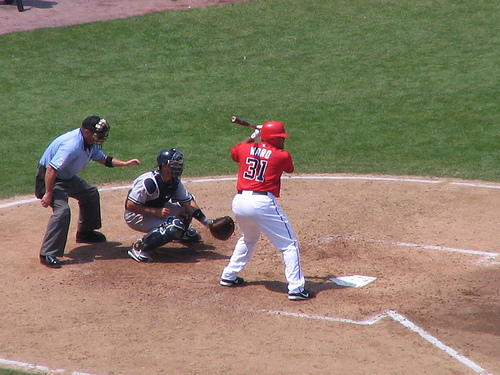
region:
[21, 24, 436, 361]
this is at a baseball field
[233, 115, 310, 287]
this is a baseball player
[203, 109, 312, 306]
this is a batter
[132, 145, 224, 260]
this is a catcher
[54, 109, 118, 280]
this is an umpire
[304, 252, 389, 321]
this is home plate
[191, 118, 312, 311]
the man is holding a bat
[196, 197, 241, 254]
this is a catchers mitt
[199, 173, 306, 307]
the man has white pants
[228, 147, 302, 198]
the man has a red jersey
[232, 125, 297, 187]
Man wearing a red jersey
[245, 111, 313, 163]
man wearing a red helmet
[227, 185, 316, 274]
man wearing white pants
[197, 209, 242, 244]
man holding a glove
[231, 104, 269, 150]
man holding a bat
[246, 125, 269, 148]
man wearing white glove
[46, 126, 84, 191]
empire with a blue shirt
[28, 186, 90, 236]
empire with gray pants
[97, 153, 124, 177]
empire wearing a wristband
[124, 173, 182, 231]
man wearing a gray jersey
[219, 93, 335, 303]
baseball batter getting ready to hit the ball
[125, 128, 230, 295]
catcher behind the batter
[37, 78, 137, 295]
referee behind the catcher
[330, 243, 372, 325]
home base in the dirt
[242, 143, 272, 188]
ward number 31 is his name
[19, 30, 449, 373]
catcher, ref and batter at home plate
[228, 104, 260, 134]
bat ready to hit ball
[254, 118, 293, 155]
red helmet on the batters head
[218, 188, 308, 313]
white baseball uniform on man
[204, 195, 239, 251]
brown glove on catchers hand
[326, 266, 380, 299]
home plate on the baseball field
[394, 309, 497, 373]
white chalk lines on field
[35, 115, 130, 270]
the umpire of game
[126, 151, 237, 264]
catcher for pitching team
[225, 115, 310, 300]
the batter for team hitting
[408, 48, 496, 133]
fresh cut green grass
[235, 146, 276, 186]
Player's last name and number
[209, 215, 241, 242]
catchers mitt on left hand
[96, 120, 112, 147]
mask worn by umpire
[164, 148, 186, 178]
mask worn by catcher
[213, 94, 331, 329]
a baseball player wearing a red uniform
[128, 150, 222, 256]
a catcher wearing a grey uniform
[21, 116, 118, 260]
an umpire wearing a blue shirt and grey pants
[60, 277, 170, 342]
brown dirt of the baseball diamond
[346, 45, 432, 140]
green grass of the baseball field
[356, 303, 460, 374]
white lines of the baseball diamond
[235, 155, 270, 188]
black numbers on the batter's red shirt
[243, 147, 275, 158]
white letters on the batter's red shirt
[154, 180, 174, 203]
the catcher's black pads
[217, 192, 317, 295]
the batter's white baseball pants